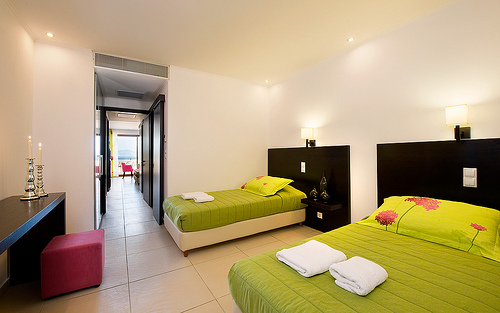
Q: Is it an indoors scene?
A: Yes, it is indoors.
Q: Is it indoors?
A: Yes, it is indoors.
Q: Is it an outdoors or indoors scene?
A: It is indoors.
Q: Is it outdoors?
A: No, it is indoors.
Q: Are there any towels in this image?
A: Yes, there is a towel.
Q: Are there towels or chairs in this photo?
A: Yes, there is a towel.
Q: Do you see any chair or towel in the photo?
A: Yes, there is a towel.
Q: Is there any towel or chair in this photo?
A: Yes, there is a towel.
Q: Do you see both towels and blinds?
A: No, there is a towel but no blinds.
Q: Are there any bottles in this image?
A: No, there are no bottles.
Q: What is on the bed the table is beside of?
A: The towel is on the bed.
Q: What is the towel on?
A: The towel is on the bed.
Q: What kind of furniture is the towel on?
A: The towel is on the bed.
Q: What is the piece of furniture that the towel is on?
A: The piece of furniture is a bed.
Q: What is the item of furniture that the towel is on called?
A: The piece of furniture is a bed.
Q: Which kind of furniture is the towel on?
A: The towel is on the bed.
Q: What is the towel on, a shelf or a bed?
A: The towel is on a bed.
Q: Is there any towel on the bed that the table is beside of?
A: Yes, there is a towel on the bed.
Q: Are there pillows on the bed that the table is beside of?
A: No, there is a towel on the bed.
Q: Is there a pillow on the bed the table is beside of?
A: No, there is a towel on the bed.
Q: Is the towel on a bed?
A: Yes, the towel is on a bed.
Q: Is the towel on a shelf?
A: No, the towel is on a bed.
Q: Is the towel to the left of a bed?
A: Yes, the towel is to the left of a bed.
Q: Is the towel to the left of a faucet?
A: No, the towel is to the left of a bed.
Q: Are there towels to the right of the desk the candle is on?
A: Yes, there is a towel to the right of the desk.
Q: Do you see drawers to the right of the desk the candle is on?
A: No, there is a towel to the right of the desk.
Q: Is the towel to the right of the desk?
A: Yes, the towel is to the right of the desk.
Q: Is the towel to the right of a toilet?
A: No, the towel is to the right of the desk.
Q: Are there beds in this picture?
A: Yes, there is a bed.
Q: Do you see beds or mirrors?
A: Yes, there is a bed.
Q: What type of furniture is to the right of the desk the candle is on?
A: The piece of furniture is a bed.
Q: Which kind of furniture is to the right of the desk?
A: The piece of furniture is a bed.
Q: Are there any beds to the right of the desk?
A: Yes, there is a bed to the right of the desk.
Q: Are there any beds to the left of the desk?
A: No, the bed is to the right of the desk.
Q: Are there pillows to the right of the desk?
A: No, there is a bed to the right of the desk.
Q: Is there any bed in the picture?
A: Yes, there is a bed.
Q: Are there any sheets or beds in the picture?
A: Yes, there is a bed.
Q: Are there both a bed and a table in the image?
A: Yes, there are both a bed and a table.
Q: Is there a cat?
A: No, there are no cats.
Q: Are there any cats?
A: No, there are no cats.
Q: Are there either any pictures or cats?
A: No, there are no cats or pictures.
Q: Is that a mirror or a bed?
A: That is a bed.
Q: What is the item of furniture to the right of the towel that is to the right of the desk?
A: The piece of furniture is a bed.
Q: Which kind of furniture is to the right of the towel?
A: The piece of furniture is a bed.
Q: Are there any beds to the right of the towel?
A: Yes, there is a bed to the right of the towel.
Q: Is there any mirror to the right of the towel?
A: No, there is a bed to the right of the towel.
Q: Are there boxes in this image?
A: No, there are no boxes.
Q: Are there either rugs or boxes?
A: No, there are no boxes or rugs.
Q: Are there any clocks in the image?
A: No, there are no clocks.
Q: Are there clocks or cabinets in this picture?
A: No, there are no clocks or cabinets.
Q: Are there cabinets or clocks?
A: No, there are no clocks or cabinets.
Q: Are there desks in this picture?
A: Yes, there is a desk.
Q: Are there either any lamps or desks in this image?
A: Yes, there is a desk.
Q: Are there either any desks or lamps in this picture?
A: Yes, there is a desk.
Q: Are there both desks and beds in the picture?
A: Yes, there are both a desk and a bed.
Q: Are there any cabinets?
A: No, there are no cabinets.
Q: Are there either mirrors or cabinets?
A: No, there are no cabinets or mirrors.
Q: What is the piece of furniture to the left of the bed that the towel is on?
A: The piece of furniture is a desk.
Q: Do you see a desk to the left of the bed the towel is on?
A: Yes, there is a desk to the left of the bed.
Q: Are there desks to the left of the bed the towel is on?
A: Yes, there is a desk to the left of the bed.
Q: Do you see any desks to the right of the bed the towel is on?
A: No, the desk is to the left of the bed.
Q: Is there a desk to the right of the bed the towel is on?
A: No, the desk is to the left of the bed.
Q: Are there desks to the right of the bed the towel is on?
A: No, the desk is to the left of the bed.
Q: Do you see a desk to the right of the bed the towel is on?
A: No, the desk is to the left of the bed.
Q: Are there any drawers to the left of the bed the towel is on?
A: No, there is a desk to the left of the bed.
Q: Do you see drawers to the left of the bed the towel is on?
A: No, there is a desk to the left of the bed.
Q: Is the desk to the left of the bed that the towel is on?
A: Yes, the desk is to the left of the bed.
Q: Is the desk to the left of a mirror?
A: No, the desk is to the left of the bed.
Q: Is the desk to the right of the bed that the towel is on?
A: No, the desk is to the left of the bed.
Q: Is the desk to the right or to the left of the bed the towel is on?
A: The desk is to the left of the bed.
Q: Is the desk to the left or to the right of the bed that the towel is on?
A: The desk is to the left of the bed.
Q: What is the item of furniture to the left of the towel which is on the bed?
A: The piece of furniture is a desk.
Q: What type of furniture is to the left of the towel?
A: The piece of furniture is a desk.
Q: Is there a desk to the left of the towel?
A: Yes, there is a desk to the left of the towel.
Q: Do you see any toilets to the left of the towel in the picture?
A: No, there is a desk to the left of the towel.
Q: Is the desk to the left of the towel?
A: Yes, the desk is to the left of the towel.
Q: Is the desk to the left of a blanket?
A: No, the desk is to the left of the towel.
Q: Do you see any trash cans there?
A: No, there are no trash cans.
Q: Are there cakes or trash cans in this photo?
A: No, there are no trash cans or cakes.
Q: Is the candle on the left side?
A: Yes, the candle is on the left of the image.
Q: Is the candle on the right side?
A: No, the candle is on the left of the image.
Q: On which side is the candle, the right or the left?
A: The candle is on the left of the image.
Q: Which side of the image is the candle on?
A: The candle is on the left of the image.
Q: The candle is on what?
A: The candle is on the desk.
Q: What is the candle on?
A: The candle is on the desk.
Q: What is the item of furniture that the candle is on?
A: The piece of furniture is a desk.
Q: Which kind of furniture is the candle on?
A: The candle is on the desk.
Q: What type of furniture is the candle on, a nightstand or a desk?
A: The candle is on a desk.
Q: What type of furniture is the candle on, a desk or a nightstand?
A: The candle is on a desk.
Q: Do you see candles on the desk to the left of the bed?
A: Yes, there is a candle on the desk.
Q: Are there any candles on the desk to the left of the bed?
A: Yes, there is a candle on the desk.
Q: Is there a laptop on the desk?
A: No, there is a candle on the desk.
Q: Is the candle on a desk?
A: Yes, the candle is on a desk.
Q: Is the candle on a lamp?
A: No, the candle is on a desk.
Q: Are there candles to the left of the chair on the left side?
A: Yes, there is a candle to the left of the chair.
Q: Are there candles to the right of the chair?
A: No, the candle is to the left of the chair.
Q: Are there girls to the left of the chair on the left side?
A: No, there is a candle to the left of the chair.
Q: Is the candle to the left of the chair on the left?
A: Yes, the candle is to the left of the chair.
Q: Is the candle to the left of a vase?
A: No, the candle is to the left of the chair.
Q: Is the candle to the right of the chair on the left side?
A: No, the candle is to the left of the chair.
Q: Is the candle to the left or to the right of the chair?
A: The candle is to the left of the chair.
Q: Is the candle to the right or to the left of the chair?
A: The candle is to the left of the chair.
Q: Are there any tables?
A: Yes, there is a table.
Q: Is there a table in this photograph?
A: Yes, there is a table.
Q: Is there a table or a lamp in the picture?
A: Yes, there is a table.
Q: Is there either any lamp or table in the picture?
A: Yes, there is a table.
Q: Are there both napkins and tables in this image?
A: No, there is a table but no napkins.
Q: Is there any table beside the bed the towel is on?
A: Yes, there is a table beside the bed.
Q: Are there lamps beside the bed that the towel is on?
A: No, there is a table beside the bed.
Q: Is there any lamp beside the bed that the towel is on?
A: No, there is a table beside the bed.